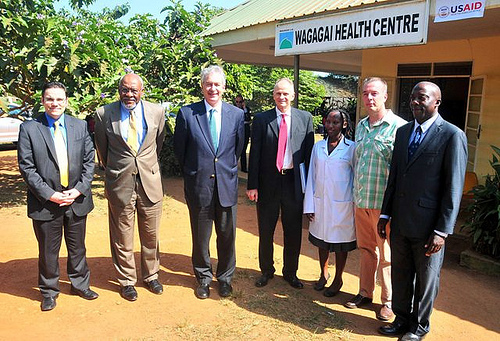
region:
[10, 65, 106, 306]
A man in a black suit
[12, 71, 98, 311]
A man with a yellow tie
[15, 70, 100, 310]
A man with glasses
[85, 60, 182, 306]
A man in a brown suit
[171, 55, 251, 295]
A man with a blue tie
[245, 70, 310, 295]
A man with a pink tie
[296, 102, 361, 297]
A woman in a white labcoat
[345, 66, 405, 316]
A man with a green/white shirt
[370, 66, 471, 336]
A man with a dark blue tie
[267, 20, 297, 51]
A green/blue logo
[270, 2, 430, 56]
A sign that reads "WAGAGAI HEALTH CENTRE"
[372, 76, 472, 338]
A man wearing a suit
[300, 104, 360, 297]
Woman wearing a white coat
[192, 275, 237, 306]
A pair of black shoes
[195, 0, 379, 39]
Roof of a building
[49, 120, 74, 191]
A yellow colored tie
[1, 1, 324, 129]
Green leaves on trees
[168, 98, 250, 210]
A navy blue jacket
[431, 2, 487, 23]
A small white sign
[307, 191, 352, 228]
Two pockets on white coat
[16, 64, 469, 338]
Seven people in front of the Waggagai Health Centre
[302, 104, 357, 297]
Woman wearing white lab coat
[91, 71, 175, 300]
Man wearing brown suit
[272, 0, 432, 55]
Signage for Wagagai Health Centre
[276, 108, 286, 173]
Red tie around man's neck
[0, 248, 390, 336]
People's shadows in the dirt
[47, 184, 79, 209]
Clasped hands of man on the left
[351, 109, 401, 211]
Green plaid shirt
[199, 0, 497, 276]
The Wagagai Health Centre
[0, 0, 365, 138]
Trees and shrubbery in the background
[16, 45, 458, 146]
People are smiling in the shot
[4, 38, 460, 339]
Everyone is professionally dressed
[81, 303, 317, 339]
This is a dirt road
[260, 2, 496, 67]
A sign underneath the roof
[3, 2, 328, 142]
Tropical trees in the path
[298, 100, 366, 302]
Only one woman in the shot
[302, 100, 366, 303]
Her skin is dark brown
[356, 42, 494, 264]
The building is light brown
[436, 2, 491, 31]
"US AID" on the sign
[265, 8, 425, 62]
"Wagagai Health Center"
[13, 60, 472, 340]
Seven people are posing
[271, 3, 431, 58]
Sign hanging on a building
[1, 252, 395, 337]
Shadows on the ground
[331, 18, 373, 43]
The word 'HEALTH" on a sign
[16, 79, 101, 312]
A man in a suit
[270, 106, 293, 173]
A pink colored tie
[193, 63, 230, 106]
White hair on man's head